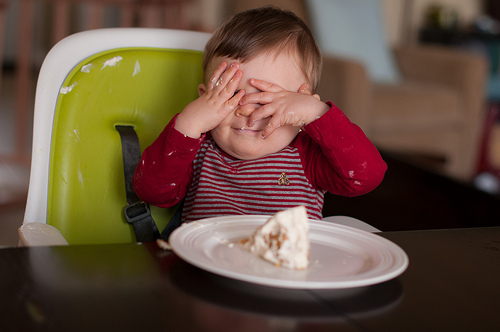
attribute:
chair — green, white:
[15, 20, 247, 236]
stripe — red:
[199, 170, 309, 182]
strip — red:
[254, 150, 310, 188]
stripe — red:
[195, 181, 313, 198]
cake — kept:
[244, 203, 311, 268]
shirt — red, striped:
[130, 98, 387, 223]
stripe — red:
[194, 153, 300, 159]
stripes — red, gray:
[194, 144, 327, 221]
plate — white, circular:
[173, 203, 408, 288]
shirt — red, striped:
[142, 129, 374, 218]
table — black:
[3, 220, 498, 324]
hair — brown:
[208, 13, 325, 64]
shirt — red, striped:
[152, 110, 372, 232]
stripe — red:
[178, 201, 239, 210]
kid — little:
[136, 15, 423, 248]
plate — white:
[187, 219, 416, 299]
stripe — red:
[196, 148, 217, 155]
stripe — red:
[204, 160, 293, 170]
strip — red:
[212, 161, 261, 194]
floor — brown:
[320, 147, 498, 230]